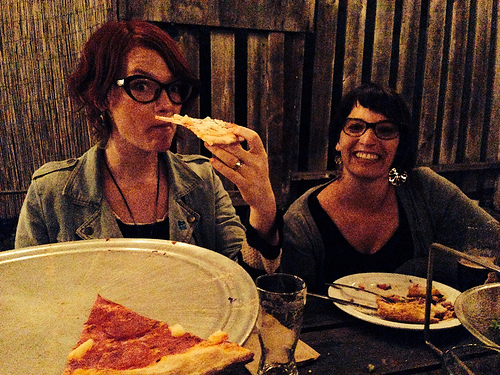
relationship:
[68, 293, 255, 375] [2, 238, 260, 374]
pizza on pan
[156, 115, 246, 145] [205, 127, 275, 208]
pizza in hand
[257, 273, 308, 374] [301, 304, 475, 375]
glass on table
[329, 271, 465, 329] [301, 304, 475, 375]
plate on table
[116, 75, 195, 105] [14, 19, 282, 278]
glasses on woman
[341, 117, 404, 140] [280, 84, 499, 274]
glasses on woman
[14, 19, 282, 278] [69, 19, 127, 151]
woman has brown hair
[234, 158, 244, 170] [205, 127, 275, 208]
ring on hand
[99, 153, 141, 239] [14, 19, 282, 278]
nacklace on woman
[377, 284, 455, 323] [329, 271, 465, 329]
food on plate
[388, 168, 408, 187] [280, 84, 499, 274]
earring on woman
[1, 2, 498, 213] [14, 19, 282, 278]
wall behind woman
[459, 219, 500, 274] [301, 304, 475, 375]
glass on table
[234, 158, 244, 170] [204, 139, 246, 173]
ring on finger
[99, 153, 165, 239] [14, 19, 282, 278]
nacklace on woman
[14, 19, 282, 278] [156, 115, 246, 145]
woman eating pizza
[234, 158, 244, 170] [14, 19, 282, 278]
ring on woman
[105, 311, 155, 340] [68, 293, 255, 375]
pepperoni on pizza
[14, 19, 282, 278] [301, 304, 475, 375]
woman at table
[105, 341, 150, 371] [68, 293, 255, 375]
pepperoni on pizza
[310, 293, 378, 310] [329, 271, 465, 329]
utensil on plate